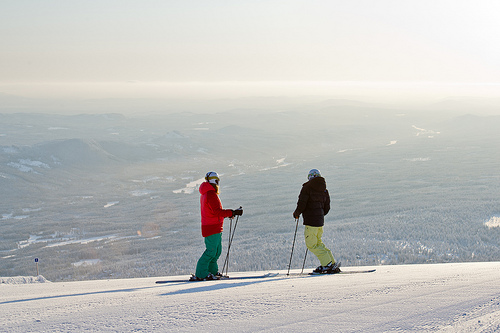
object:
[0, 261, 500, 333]
mountain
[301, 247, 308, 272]
ski poles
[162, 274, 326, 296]
shadow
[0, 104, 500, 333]
ground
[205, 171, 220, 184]
head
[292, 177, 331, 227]
jacket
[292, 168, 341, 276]
person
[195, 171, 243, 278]
person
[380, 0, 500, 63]
light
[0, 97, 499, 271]
mountains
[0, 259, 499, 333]
snow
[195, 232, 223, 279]
green pants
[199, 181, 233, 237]
coat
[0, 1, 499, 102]
sky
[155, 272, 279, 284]
skis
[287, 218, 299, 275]
poles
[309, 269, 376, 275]
skis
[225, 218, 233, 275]
ski pole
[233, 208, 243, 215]
hand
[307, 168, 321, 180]
hat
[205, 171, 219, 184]
hat